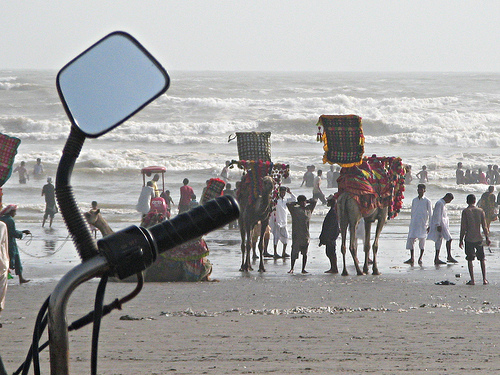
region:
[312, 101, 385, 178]
seat on the camel.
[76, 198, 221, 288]
Camel sitting on the beach.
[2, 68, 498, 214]
Water in the background.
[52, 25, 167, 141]
mirror attached to handle bar.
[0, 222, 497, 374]
Sand on the beach.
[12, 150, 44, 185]
People in the water.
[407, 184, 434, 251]
white tunic on the man.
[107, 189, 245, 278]
Black grip on the handle bar.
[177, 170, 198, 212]
Person in a red shirt.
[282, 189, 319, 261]
Man in a brown tunic.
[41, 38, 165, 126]
the mirror of a motorcycle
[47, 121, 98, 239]
the stick for a window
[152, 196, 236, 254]
the handle on a motorcycle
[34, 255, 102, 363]
the handlebar of a motorcycle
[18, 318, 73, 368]
the brake wires of a motorcycle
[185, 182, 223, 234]
the padding on the handles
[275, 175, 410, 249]
a group of people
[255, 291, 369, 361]
a bunch of beach sand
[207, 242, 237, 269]
the ocean water meeting the sand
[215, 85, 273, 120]
a bunch of white foam waves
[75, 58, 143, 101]
Glass on the side mirror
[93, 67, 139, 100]
Blue sky reflected on mirror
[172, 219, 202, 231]
The handle bar of the motorbike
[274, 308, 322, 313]
Trash on the beach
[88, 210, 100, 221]
Head of a camel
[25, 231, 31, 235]
Hand holding a tether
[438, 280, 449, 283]
A dark piece of trash on the shore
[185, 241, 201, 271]
Saddling cloth on a camel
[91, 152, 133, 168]
Waves breaking on the shore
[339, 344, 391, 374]
A wet sandy beach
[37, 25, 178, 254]
rear view mirror on motorcycle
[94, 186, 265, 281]
handlebar on motorcycle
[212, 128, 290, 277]
camel on sand in front of water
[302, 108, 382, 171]
chair on top of camel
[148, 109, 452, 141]
large white wave in ocean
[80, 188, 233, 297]
camel lying down in wet sand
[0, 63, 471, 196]
body of water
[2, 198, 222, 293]
man holding rope attached to camel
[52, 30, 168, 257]
rear view mirror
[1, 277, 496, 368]
sandy beach near the ocean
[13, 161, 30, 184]
person in the ocean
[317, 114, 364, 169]
blanket with yellow edge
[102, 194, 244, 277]
blank handle bar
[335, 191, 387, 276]
camel on the beach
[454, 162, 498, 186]
group of people in the water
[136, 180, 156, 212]
person inlong white coat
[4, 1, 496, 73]
section of an overcast sky